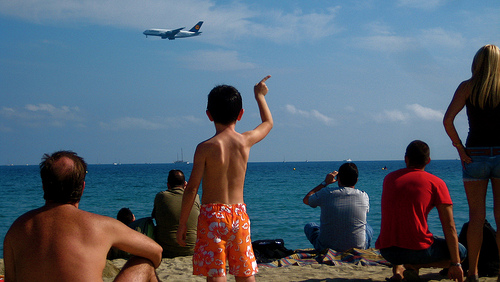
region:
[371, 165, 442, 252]
the t-shirt is red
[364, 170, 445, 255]
the t-shirt is red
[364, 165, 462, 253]
the t-shirt is red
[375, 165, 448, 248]
the t-shirt is red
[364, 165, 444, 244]
the t-shirt is red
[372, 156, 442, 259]
the t-shirt is red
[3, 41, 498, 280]
group of people at the beach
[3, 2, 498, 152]
airplane flying in the sky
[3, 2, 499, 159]
clouds in the sky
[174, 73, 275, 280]
boy with orange swim trunks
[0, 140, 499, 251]
boats in the ocean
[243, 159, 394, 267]
man sitting on a blanket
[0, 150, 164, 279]
man with bald spot on head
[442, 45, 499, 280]
woman wearing blue shorts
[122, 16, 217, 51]
the plane is flying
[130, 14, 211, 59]
the plane is flying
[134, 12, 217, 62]
the plane is flying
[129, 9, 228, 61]
the plane is flying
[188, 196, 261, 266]
boy's shorts are orange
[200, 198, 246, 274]
boy's shorts are orange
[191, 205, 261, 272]
boy's shorts are orange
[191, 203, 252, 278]
boy's shorts are orange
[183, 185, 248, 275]
boy's shorts are orange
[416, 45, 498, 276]
lady standing on the beach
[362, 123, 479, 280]
man wearing red shirt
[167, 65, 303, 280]
little boy wearing orange shorts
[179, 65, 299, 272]
little boy pointing at sky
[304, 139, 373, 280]
man taking a picture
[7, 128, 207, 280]
man with no shirt sitting on beach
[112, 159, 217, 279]
man sitting on the beach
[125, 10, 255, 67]
plane in the sky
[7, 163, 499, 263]
blue sea water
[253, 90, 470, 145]
clouds in the sky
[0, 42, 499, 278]
People on the beach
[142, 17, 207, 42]
Airplane flying in the sky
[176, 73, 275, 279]
Boy wearing orange print swimsuit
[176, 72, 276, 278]
Boy pointing to the sky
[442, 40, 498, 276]
Blonde-haired woman with left hand in back pocket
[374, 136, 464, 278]
Man in red shirt kneeling in the sand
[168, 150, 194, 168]
Boat on the water in the distance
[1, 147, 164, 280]
Shirtless man sitting in the sand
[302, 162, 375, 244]
Man in blue shirt sitting in the sand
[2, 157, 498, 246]
Calm blue water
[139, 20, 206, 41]
Passenger plane flying in the air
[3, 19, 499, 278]
People on beach watching passenger plane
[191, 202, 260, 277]
Boy's orange and white hawaiian shorts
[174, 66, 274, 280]
Boy pointing into the sky